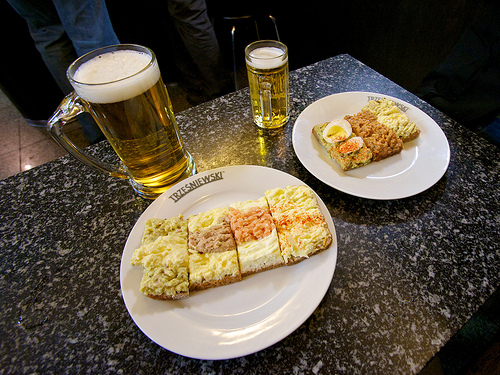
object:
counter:
[0, 53, 498, 374]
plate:
[118, 164, 339, 358]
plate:
[293, 90, 451, 200]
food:
[131, 185, 334, 302]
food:
[310, 99, 423, 171]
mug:
[244, 39, 292, 130]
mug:
[45, 42, 198, 204]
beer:
[253, 58, 282, 123]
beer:
[92, 70, 156, 118]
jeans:
[11, 0, 119, 149]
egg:
[323, 117, 352, 143]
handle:
[259, 82, 273, 123]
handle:
[46, 91, 125, 185]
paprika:
[339, 136, 367, 155]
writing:
[169, 171, 224, 204]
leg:
[177, 0, 225, 97]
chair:
[221, 2, 286, 90]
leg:
[228, 24, 239, 88]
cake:
[363, 100, 420, 143]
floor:
[0, 92, 90, 178]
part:
[199, 295, 277, 338]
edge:
[338, 188, 430, 203]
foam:
[245, 45, 287, 69]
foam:
[70, 50, 160, 105]